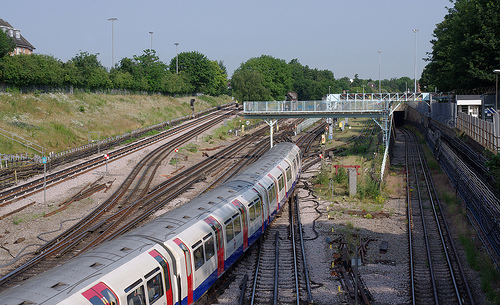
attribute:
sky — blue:
[323, 20, 415, 68]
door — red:
[209, 226, 227, 266]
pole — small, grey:
[348, 168, 361, 198]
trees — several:
[42, 52, 173, 88]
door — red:
[201, 215, 232, 281]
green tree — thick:
[441, 23, 483, 67]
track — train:
[402, 131, 469, 303]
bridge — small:
[244, 99, 396, 142]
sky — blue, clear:
[8, 2, 465, 78]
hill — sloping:
[2, 80, 238, 194]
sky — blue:
[5, 1, 468, 95]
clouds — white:
[323, 30, 366, 62]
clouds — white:
[358, 16, 398, 59]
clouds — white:
[304, 29, 396, 55]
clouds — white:
[219, 23, 300, 53]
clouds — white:
[168, 39, 224, 59]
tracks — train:
[234, 111, 478, 302]